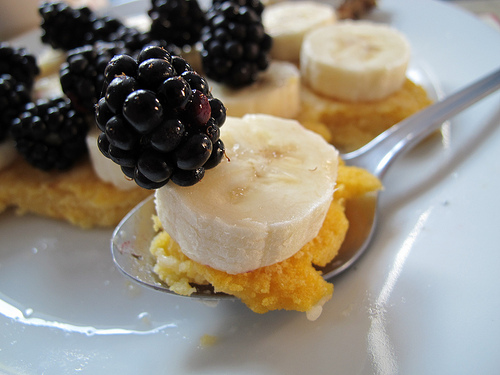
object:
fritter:
[141, 233, 353, 321]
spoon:
[102, 59, 500, 302]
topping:
[2, 0, 446, 230]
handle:
[351, 65, 496, 184]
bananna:
[147, 108, 345, 275]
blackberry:
[88, 39, 231, 196]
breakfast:
[0, 0, 461, 325]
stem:
[220, 147, 232, 164]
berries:
[117, 84, 168, 136]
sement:
[182, 93, 215, 128]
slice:
[146, 107, 344, 280]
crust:
[140, 159, 387, 325]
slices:
[290, 13, 421, 106]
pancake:
[4, 0, 442, 242]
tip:
[107, 225, 145, 261]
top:
[157, 109, 344, 232]